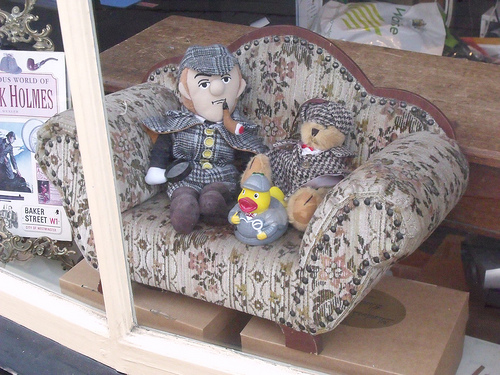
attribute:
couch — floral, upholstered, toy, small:
[34, 23, 473, 358]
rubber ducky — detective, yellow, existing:
[227, 172, 291, 248]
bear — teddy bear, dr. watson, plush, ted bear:
[237, 97, 361, 234]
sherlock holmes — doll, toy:
[138, 41, 268, 234]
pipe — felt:
[221, 99, 245, 139]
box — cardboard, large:
[238, 275, 474, 374]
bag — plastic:
[308, 0, 463, 57]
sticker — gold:
[337, 287, 405, 331]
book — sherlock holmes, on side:
[0, 50, 74, 243]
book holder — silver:
[1, 0, 79, 271]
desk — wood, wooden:
[95, 12, 498, 242]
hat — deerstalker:
[179, 45, 237, 77]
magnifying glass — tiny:
[250, 218, 265, 234]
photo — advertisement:
[1, 0, 500, 373]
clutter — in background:
[289, 2, 499, 67]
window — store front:
[0, 0, 498, 374]